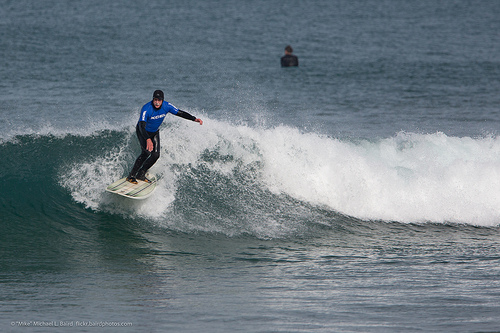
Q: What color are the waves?
A: White.